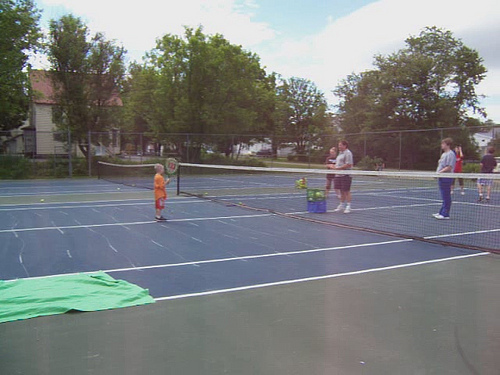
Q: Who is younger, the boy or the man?
A: The boy is younger than the man.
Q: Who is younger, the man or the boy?
A: The boy is younger than the man.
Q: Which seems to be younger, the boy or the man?
A: The boy is younger than the man.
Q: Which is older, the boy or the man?
A: The man is older than the boy.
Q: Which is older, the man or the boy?
A: The man is older than the boy.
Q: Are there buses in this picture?
A: No, there are no buses.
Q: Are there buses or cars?
A: No, there are no buses or cars.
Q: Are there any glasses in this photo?
A: No, there are no glasses.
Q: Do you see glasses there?
A: No, there are no glasses.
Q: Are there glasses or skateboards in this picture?
A: No, there are no glasses or skateboards.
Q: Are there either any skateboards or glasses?
A: No, there are no glasses or skateboards.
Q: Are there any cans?
A: No, there are no cans.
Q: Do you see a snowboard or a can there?
A: No, there are no cans or snowboards.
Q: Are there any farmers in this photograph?
A: No, there are no farmers.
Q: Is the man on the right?
A: Yes, the man is on the right of the image.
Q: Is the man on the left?
A: No, the man is on the right of the image.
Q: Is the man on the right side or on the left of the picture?
A: The man is on the right of the image.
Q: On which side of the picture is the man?
A: The man is on the right of the image.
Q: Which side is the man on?
A: The man is on the right of the image.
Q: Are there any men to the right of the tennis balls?
A: Yes, there is a man to the right of the tennis balls.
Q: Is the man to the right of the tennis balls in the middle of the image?
A: Yes, the man is to the right of the tennis balls.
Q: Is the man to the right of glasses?
A: No, the man is to the right of the tennis balls.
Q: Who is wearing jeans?
A: The man is wearing jeans.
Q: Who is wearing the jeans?
A: The man is wearing jeans.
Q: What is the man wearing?
A: The man is wearing jeans.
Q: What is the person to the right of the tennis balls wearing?
A: The man is wearing jeans.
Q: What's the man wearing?
A: The man is wearing jeans.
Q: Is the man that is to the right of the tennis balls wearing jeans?
A: Yes, the man is wearing jeans.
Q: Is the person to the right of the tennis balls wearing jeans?
A: Yes, the man is wearing jeans.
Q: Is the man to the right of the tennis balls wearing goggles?
A: No, the man is wearing jeans.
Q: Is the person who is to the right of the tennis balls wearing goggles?
A: No, the man is wearing jeans.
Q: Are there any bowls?
A: No, there are no bowls.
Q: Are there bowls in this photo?
A: No, there are no bowls.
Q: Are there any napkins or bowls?
A: No, there are no bowls or napkins.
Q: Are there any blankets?
A: Yes, there is a blanket.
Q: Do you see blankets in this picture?
A: Yes, there is a blanket.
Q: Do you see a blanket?
A: Yes, there is a blanket.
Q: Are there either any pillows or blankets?
A: Yes, there is a blanket.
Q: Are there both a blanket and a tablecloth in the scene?
A: No, there is a blanket but no tablecloths.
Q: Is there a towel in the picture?
A: No, there are no towels.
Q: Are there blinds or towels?
A: No, there are no towels or blinds.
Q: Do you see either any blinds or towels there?
A: No, there are no towels or blinds.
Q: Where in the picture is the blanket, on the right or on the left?
A: The blanket is on the left of the image.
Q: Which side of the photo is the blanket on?
A: The blanket is on the left of the image.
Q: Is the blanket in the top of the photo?
A: No, the blanket is in the bottom of the image.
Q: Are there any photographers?
A: No, there are no photographers.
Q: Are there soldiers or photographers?
A: No, there are no photographers or soldiers.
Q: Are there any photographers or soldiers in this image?
A: No, there are no photographers or soldiers.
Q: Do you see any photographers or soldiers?
A: No, there are no photographers or soldiers.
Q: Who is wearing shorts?
A: The boy is wearing shorts.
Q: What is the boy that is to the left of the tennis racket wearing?
A: The boy is wearing shorts.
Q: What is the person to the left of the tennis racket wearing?
A: The boy is wearing shorts.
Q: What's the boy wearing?
A: The boy is wearing shorts.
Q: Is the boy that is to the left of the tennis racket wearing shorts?
A: Yes, the boy is wearing shorts.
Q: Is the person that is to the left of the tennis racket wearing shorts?
A: Yes, the boy is wearing shorts.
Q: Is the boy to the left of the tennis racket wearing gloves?
A: No, the boy is wearing shorts.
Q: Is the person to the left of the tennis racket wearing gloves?
A: No, the boy is wearing shorts.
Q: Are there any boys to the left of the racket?
A: Yes, there is a boy to the left of the racket.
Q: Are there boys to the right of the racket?
A: No, the boy is to the left of the racket.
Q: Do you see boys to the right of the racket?
A: No, the boy is to the left of the racket.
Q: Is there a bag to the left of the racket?
A: No, there is a boy to the left of the racket.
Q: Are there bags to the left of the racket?
A: No, there is a boy to the left of the racket.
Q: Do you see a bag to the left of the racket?
A: No, there is a boy to the left of the racket.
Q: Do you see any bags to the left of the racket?
A: No, there is a boy to the left of the racket.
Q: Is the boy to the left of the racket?
A: Yes, the boy is to the left of the racket.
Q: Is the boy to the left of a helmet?
A: No, the boy is to the left of the racket.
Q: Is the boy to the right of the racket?
A: No, the boy is to the left of the racket.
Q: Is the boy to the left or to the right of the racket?
A: The boy is to the left of the racket.